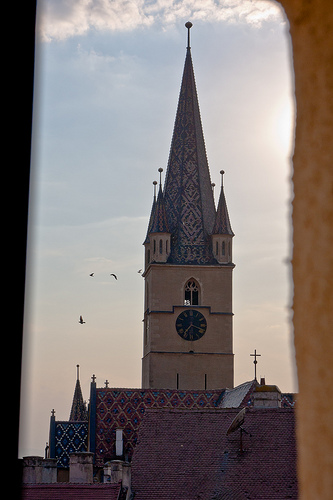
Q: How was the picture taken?
A: Through a window.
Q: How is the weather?
A: Clear.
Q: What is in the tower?
A: A clock.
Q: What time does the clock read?
A: 7:20.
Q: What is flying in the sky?
A: Birds.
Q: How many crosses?
A: One.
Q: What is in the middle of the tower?
A: Clock.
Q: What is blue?
A: The sky.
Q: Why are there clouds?
A: The weather.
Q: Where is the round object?
A: On the top of the tallest tower.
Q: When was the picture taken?
A: Daytime.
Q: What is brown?
A: Rooftops.